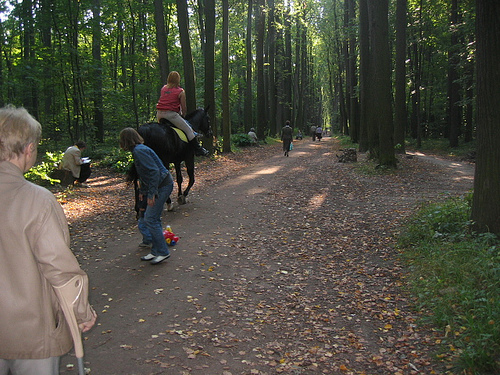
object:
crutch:
[50, 274, 88, 375]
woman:
[0, 104, 98, 374]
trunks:
[366, 0, 379, 158]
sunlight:
[308, 193, 327, 210]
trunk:
[371, 0, 396, 169]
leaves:
[270, 180, 408, 375]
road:
[45, 134, 474, 375]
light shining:
[279, 0, 336, 27]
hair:
[167, 71, 181, 87]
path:
[59, 132, 476, 375]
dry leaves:
[271, 191, 394, 367]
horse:
[125, 104, 212, 218]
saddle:
[159, 117, 174, 126]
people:
[120, 127, 174, 264]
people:
[281, 121, 294, 157]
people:
[0, 103, 96, 375]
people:
[155, 70, 209, 155]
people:
[248, 128, 258, 143]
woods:
[0, 0, 500, 249]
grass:
[395, 191, 499, 374]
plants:
[399, 190, 499, 375]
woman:
[118, 126, 175, 265]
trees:
[468, 0, 500, 234]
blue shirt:
[132, 144, 173, 199]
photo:
[0, 0, 493, 367]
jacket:
[132, 144, 173, 198]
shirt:
[156, 84, 184, 112]